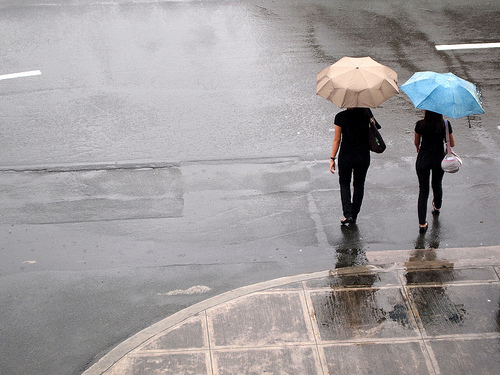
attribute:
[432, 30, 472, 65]
parking line — white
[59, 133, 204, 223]
environment — urban, rainy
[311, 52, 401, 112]
umbrella — brown, tan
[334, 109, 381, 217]
clothes — black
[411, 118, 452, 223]
clothes — black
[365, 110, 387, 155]
purse — black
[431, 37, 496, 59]
line — white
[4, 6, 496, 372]
road — wet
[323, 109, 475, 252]
pedestrians — holding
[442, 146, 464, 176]
bag — grey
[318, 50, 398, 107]
umbrella — tan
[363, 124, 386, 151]
bag — black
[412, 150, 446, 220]
pants — black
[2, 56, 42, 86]
lines — white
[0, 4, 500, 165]
road — wet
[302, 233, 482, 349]
reflection — people 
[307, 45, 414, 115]
umbrella — BROWN 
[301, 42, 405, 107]
umbrella — BROWN 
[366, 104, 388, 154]
purse — black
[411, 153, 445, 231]
pants — black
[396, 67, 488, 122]
umbrella — blue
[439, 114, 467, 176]
bag — grey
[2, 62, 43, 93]
line — white